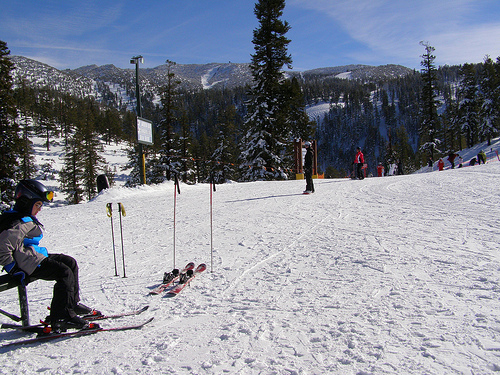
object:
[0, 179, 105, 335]
boy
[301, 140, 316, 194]
man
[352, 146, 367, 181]
woman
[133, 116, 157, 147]
sigh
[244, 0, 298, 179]
tree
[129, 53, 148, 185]
post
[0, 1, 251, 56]
sky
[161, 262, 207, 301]
ski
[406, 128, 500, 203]
slope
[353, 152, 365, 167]
jacket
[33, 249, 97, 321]
pants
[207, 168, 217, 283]
pole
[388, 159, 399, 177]
skier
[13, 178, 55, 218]
helmet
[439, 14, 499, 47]
cloud